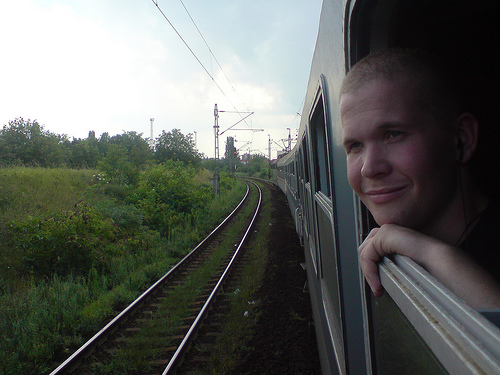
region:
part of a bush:
[108, 239, 125, 251]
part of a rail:
[191, 290, 196, 310]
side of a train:
[314, 285, 352, 309]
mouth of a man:
[376, 179, 400, 200]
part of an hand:
[451, 265, 480, 287]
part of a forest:
[135, 175, 157, 207]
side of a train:
[318, 163, 340, 178]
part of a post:
[218, 114, 222, 126]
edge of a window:
[456, 303, 486, 312]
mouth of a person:
[357, 175, 415, 210]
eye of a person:
[385, 124, 413, 144]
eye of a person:
[344, 138, 369, 157]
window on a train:
[306, 84, 333, 201]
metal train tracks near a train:
[38, 161, 266, 373]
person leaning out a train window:
[333, 28, 498, 327]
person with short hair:
[327, 37, 499, 324]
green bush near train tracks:
[123, 150, 221, 240]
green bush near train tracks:
[3, 191, 128, 276]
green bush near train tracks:
[82, 126, 149, 187]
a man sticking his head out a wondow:
[338, 58, 495, 300]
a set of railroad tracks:
[41, 170, 270, 373]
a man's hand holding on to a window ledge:
[353, 219, 488, 310]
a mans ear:
[453, 110, 483, 166]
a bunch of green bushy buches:
[1, 151, 202, 370]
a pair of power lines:
[158, 0, 268, 129]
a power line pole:
[208, 99, 242, 197]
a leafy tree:
[0, 114, 48, 163]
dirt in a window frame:
[383, 248, 494, 374]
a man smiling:
[337, 25, 498, 301]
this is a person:
[337, 31, 497, 311]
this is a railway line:
[80, 312, 195, 368]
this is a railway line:
[126, 272, 221, 347]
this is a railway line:
[178, 232, 246, 302]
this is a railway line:
[202, 210, 262, 261]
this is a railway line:
[230, 180, 263, 230]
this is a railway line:
[235, 165, 261, 201]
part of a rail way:
[161, 319, 178, 335]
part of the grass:
[86, 230, 122, 264]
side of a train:
[272, 217, 277, 260]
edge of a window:
[438, 303, 460, 328]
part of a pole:
[216, 121, 223, 139]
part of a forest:
[59, 130, 88, 150]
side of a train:
[316, 268, 343, 300]